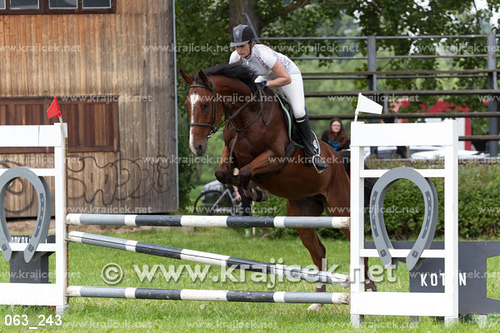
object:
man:
[229, 23, 327, 169]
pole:
[65, 212, 350, 230]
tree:
[176, 0, 500, 214]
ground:
[425, 137, 448, 160]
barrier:
[66, 212, 349, 303]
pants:
[273, 66, 314, 154]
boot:
[305, 153, 329, 169]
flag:
[353, 91, 383, 121]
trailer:
[382, 98, 478, 163]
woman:
[321, 118, 349, 152]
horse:
[178, 66, 378, 311]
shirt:
[228, 43, 294, 81]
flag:
[47, 96, 63, 122]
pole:
[65, 286, 350, 305]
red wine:
[236, 114, 279, 142]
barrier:
[0, 121, 500, 324]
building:
[0, 0, 181, 219]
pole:
[66, 229, 350, 289]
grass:
[0, 231, 500, 333]